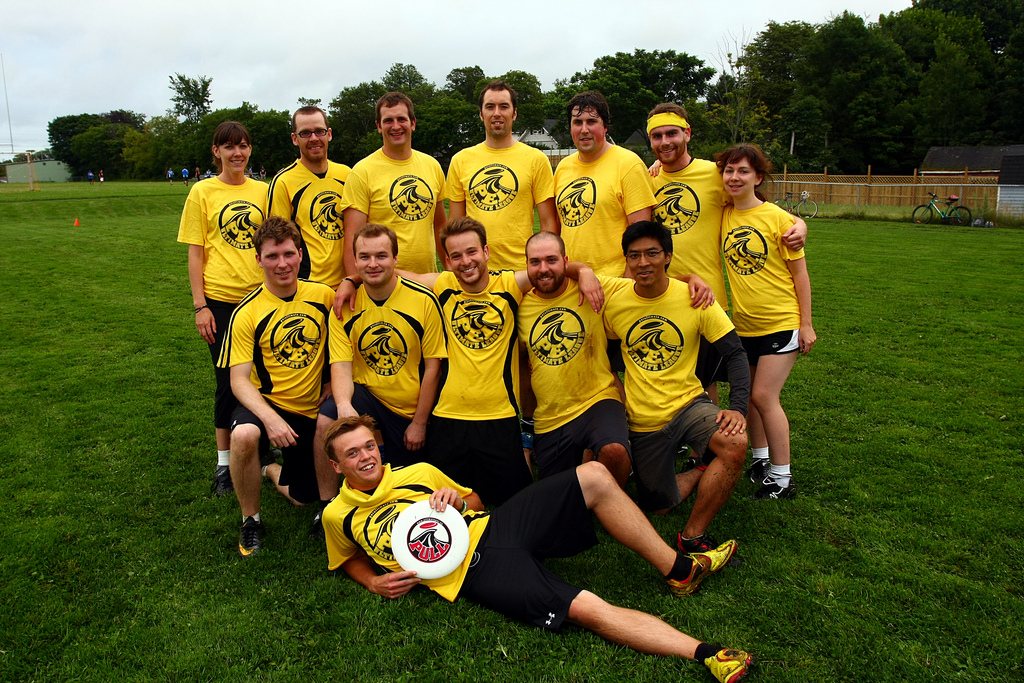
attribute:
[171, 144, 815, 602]
uniforms — yellow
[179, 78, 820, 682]
team — posing, here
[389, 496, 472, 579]
frisbee — here, white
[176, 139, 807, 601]
shirts — yellow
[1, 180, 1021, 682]
field — green, grassy, uneven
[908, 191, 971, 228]
bicycle — here, leaning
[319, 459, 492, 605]
shirt — yellow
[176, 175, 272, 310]
shirt — yellow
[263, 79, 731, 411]
men — standing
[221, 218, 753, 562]
men — kneeling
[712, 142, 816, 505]
woman — young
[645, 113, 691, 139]
sweat band — yellow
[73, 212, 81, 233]
cone — orange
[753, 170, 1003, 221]
fence — wooden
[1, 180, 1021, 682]
grass — green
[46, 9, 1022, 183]
trees — standing, distant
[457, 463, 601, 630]
shorts — black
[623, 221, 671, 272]
hair — black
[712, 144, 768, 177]
hair — brown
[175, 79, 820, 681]
group — posing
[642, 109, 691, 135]
headband — yellow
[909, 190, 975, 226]
bike — green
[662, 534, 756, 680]
shoes — yellow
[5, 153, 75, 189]
building — gray